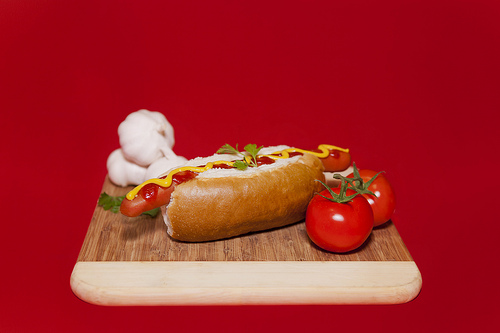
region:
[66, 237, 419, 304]
A small cutting board.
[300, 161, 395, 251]
Two whole tomatoes.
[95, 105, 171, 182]
Three heads of garlic.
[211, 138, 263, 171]
A sprig of parsley on top of the hot dog.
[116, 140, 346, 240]
A hot dog with mustard and ketchup.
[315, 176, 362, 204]
The stem of the tomato.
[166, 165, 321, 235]
The hot dog bun.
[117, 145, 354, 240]
The hot dog is larger than the bun.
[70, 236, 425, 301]
The bottom of cutting board is lighter than the rest.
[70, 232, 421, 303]
The grain of the wood is visible.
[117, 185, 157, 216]
hot dog with ketchup and mustard on bun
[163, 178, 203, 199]
hot dog with ketchup and mustard on bun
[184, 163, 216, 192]
hot dog with ketchup and mustard on bun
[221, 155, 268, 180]
hot dog with ketchup and mustard on bun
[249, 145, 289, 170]
hot dog with ketchup and mustard on bun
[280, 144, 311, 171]
hot dog with ketchup and mustard on bun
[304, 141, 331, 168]
hot dog with ketchup and mustard on bun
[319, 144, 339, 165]
hot dog with ketchup and mustard on bun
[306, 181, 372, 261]
red tomato on brown wooden board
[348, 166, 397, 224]
red tomato on brown wooden board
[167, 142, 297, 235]
hot dog with ketchup on bun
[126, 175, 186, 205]
hot dog with ketchup and mustard on bun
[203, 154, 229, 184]
hot dog with ketchup and mustard on bun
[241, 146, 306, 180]
hot dog with ketchup and mustard on bun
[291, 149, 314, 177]
hot dog with ketchup and mustard on bun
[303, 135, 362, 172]
hot dog with ketchup and mustard on bun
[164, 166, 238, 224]
hot dog with ketchup and mustard on bun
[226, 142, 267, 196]
hot dog with ketchup and mustard on bun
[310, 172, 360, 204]
Green sepal on tomato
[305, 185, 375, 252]
Red tomato next to red tomato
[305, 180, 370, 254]
Red tomato on wooden board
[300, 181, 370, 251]
Red tomato next to hot dog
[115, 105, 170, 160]
Garlic on top of another garlic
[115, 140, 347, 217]
Long sausage in bun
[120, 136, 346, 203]
Yellow mustard drizzled on long sausage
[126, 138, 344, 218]
Ketchup drizzled on long sausage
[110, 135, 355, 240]
Hot dog on wooden board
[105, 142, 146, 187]
Garlic on wooden board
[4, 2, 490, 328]
food in front of red background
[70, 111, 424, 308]
food on cutting board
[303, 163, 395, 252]
tomatoes on cutting board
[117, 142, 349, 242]
hot dog on cutting board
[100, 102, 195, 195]
garlic on cutting board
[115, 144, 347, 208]
mustard on hot dog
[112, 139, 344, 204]
ketchup on hot dog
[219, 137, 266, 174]
parsley on hot dog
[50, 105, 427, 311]
cutting board is brown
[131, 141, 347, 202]
mustard is yellow